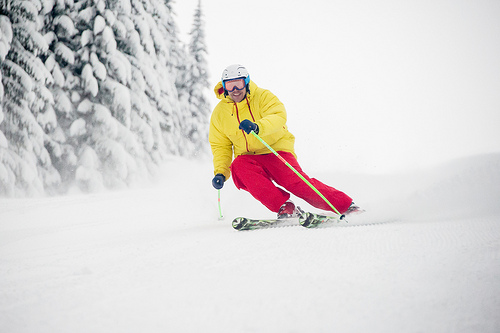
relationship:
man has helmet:
[204, 59, 386, 233] [215, 62, 261, 98]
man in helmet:
[204, 59, 386, 233] [215, 62, 261, 98]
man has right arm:
[204, 59, 386, 233] [201, 114, 238, 194]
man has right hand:
[204, 59, 386, 233] [210, 172, 229, 191]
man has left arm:
[204, 59, 386, 233] [259, 92, 291, 143]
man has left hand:
[204, 59, 386, 233] [234, 116, 262, 143]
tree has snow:
[1, 0, 62, 195] [26, 19, 52, 56]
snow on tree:
[26, 19, 52, 56] [1, 0, 62, 195]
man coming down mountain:
[204, 59, 386, 233] [2, 150, 495, 328]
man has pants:
[204, 59, 386, 233] [229, 150, 355, 221]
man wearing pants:
[204, 59, 386, 233] [229, 150, 355, 221]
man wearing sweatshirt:
[204, 59, 386, 233] [205, 77, 304, 182]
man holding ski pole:
[204, 59, 386, 233] [251, 130, 352, 227]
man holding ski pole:
[204, 59, 386, 233] [211, 177, 226, 230]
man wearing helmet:
[204, 59, 386, 233] [215, 62, 261, 98]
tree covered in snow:
[1, 0, 62, 195] [26, 19, 52, 56]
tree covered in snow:
[53, 1, 131, 201] [61, 3, 148, 197]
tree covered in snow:
[186, 0, 217, 167] [125, 2, 188, 181]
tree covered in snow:
[186, 0, 217, 167] [183, 1, 222, 171]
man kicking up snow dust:
[204, 59, 386, 233] [83, 150, 207, 216]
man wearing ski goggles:
[204, 59, 386, 233] [219, 73, 255, 96]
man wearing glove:
[204, 59, 386, 233] [235, 117, 263, 140]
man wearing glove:
[204, 59, 386, 233] [209, 172, 231, 193]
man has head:
[204, 59, 386, 233] [213, 64, 253, 105]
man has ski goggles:
[204, 59, 386, 233] [219, 73, 255, 96]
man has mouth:
[204, 59, 386, 233] [230, 90, 244, 100]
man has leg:
[204, 59, 386, 233] [226, 153, 295, 217]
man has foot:
[204, 59, 386, 233] [337, 199, 365, 223]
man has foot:
[204, 59, 386, 233] [267, 198, 312, 227]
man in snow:
[204, 59, 386, 233] [2, 147, 499, 331]